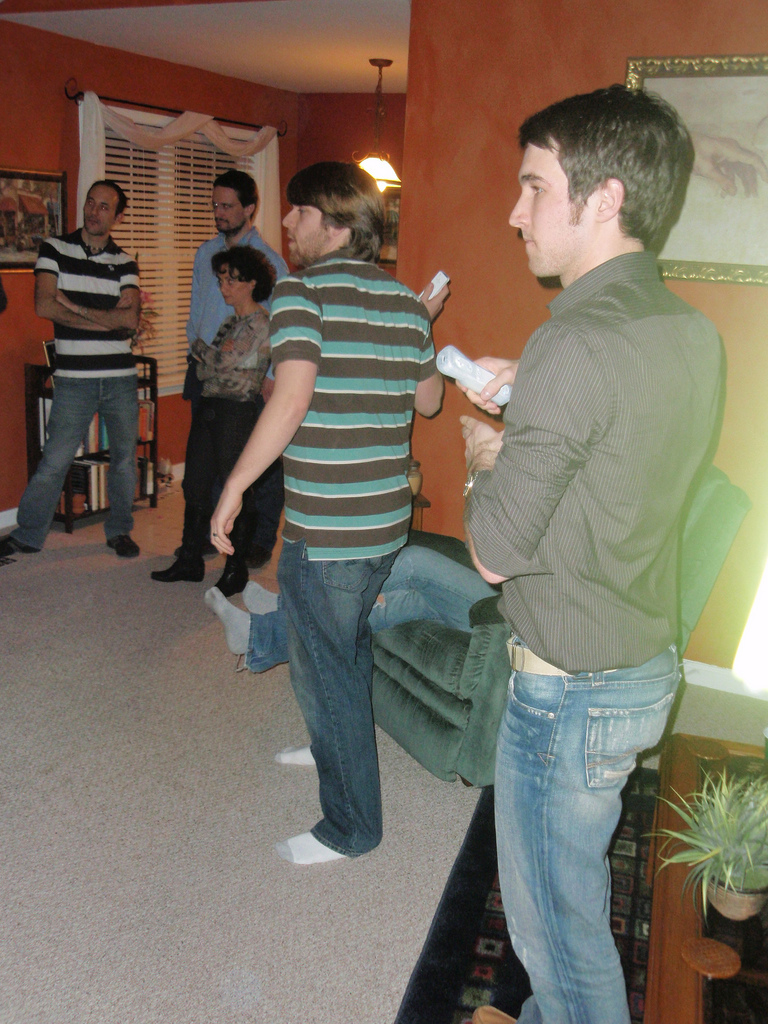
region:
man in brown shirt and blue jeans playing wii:
[451, 78, 734, 1021]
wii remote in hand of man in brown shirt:
[430, 342, 512, 406]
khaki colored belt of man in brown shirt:
[499, 626, 569, 679]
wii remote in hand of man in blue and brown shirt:
[407, 264, 450, 305]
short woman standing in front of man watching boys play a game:
[145, 245, 285, 601]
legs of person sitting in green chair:
[194, 539, 501, 667]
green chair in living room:
[328, 457, 750, 803]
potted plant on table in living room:
[654, 767, 767, 926]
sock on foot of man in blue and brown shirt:
[275, 826, 349, 864]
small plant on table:
[646, 754, 766, 936]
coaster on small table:
[674, 926, 740, 987]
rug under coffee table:
[363, 728, 681, 1020]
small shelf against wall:
[16, 337, 167, 538]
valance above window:
[69, 84, 284, 179]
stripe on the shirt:
[313, 549, 341, 563]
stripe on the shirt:
[320, 514, 344, 522]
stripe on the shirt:
[315, 495, 351, 511]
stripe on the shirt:
[311, 460, 341, 481]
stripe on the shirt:
[278, 327, 304, 346]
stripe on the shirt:
[341, 465, 376, 485]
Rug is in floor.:
[384, 832, 545, 1004]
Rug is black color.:
[382, 824, 549, 1011]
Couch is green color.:
[390, 486, 558, 808]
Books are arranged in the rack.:
[43, 353, 186, 528]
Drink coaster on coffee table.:
[674, 926, 746, 980]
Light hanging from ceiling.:
[346, 50, 405, 189]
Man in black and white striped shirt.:
[0, 174, 149, 564]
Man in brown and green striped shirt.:
[247, 157, 451, 875]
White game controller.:
[430, 338, 514, 409]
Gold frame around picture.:
[619, 51, 766, 81]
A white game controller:
[436, 345, 512, 406]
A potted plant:
[638, 752, 766, 919]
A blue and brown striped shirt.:
[264, 254, 439, 561]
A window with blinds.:
[79, 101, 283, 403]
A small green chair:
[368, 461, 753, 785]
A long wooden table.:
[643, 732, 766, 1021]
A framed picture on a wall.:
[0, 166, 66, 273]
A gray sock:
[203, 584, 250, 655]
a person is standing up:
[442, 87, 725, 1019]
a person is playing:
[427, 86, 713, 1017]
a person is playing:
[209, 149, 452, 873]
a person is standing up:
[207, 157, 443, 874]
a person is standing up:
[148, 245, 275, 590]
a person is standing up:
[174, 163, 289, 561]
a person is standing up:
[19, 179, 148, 559]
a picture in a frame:
[614, 47, 766, 287]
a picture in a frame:
[8, 168, 63, 265]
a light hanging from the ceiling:
[354, 57, 400, 194]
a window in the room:
[93, 113, 280, 375]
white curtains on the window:
[77, 94, 107, 178]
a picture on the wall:
[4, 172, 63, 271]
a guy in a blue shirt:
[194, 177, 275, 341]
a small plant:
[670, 772, 764, 906]